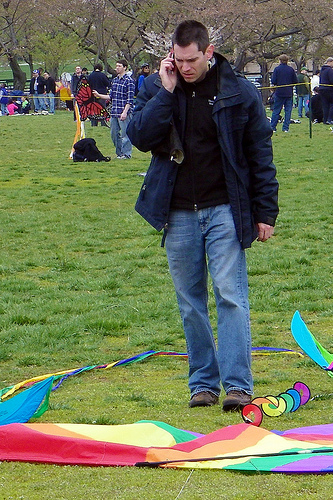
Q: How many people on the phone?
A: One.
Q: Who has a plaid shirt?
A: Man with butterfly kite.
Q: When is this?
A: Daytime.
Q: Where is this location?
A: Park.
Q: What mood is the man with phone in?
A: Not happy.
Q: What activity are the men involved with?
A: Kite flying.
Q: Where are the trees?
A: Near the crowds of people.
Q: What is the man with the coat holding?
A: Cell phone.